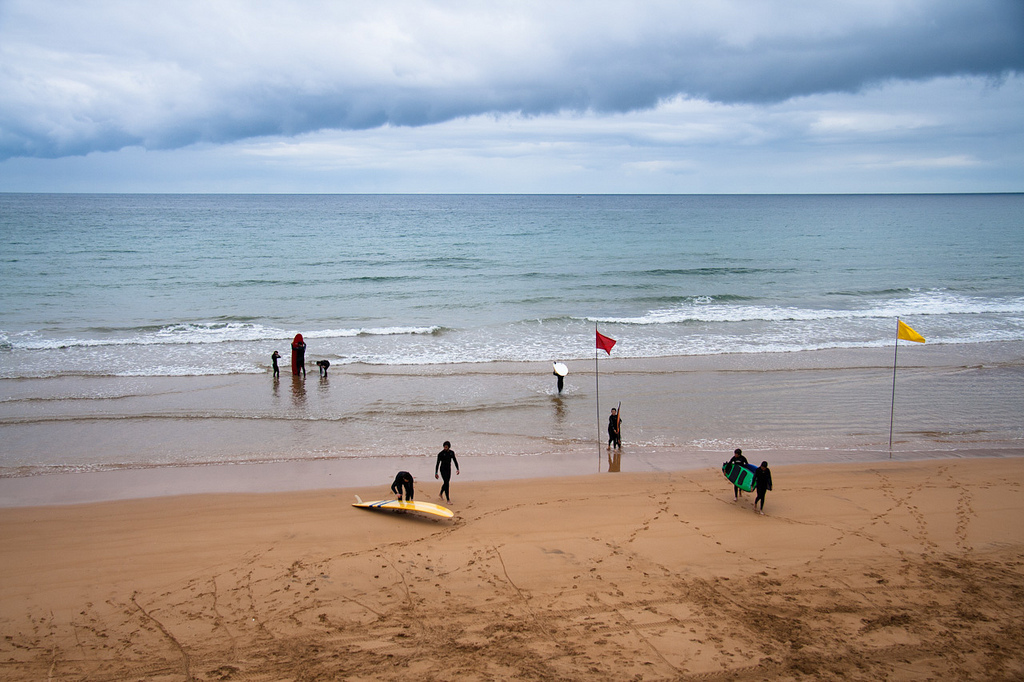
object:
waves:
[0, 297, 1024, 371]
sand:
[0, 453, 1024, 682]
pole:
[889, 316, 902, 450]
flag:
[595, 329, 617, 355]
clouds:
[0, 0, 1022, 195]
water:
[0, 194, 1024, 461]